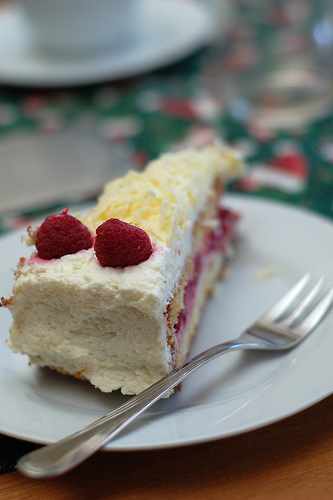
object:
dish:
[1, 188, 333, 451]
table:
[1, 2, 331, 499]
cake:
[5, 146, 243, 400]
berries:
[92, 216, 152, 268]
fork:
[13, 269, 333, 480]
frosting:
[9, 281, 171, 400]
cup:
[18, 3, 133, 58]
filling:
[165, 178, 238, 378]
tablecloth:
[0, 0, 333, 239]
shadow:
[1, 395, 333, 500]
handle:
[18, 339, 233, 482]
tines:
[267, 272, 310, 320]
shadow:
[105, 339, 284, 444]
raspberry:
[21, 207, 94, 259]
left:
[0, 0, 169, 499]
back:
[6, 279, 171, 398]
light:
[267, 269, 333, 328]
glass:
[217, 0, 332, 138]